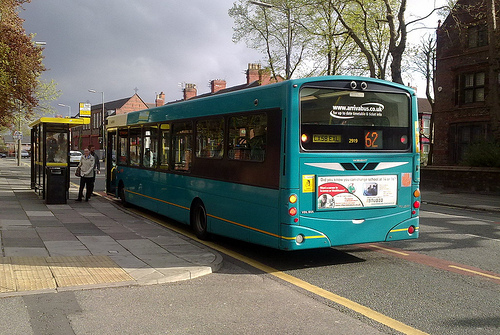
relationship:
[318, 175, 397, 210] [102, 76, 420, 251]
ad on bus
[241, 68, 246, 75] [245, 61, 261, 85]
spikes on chimney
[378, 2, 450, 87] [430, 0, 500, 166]
tree next to building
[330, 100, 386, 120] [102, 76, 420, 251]
website address on bus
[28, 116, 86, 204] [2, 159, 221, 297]
bus stop on sidewalk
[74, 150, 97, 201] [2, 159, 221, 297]
man on sidewalk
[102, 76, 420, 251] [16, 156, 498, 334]
bus on street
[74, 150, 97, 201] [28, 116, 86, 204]
man at bus stop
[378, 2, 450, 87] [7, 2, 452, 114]
tree in front of sky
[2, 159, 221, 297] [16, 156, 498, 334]
sidewalk next to street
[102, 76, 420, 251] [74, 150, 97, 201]
bus dropping off man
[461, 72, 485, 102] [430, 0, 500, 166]
window on building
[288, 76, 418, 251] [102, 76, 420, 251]
rear of bus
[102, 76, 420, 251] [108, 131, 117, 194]
bus has door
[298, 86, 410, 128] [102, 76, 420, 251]
rear windshield of bus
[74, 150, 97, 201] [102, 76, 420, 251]
man standing by bus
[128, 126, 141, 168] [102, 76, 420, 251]
passenger window of bus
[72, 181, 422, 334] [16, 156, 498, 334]
stripe on street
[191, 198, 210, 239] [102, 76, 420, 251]
tire of bus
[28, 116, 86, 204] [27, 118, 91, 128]
bus stop has overhang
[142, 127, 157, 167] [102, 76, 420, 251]
window of bus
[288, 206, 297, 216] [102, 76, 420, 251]
tail light of bus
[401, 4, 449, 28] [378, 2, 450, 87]
branch of tree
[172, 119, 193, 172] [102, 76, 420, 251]
window of bus